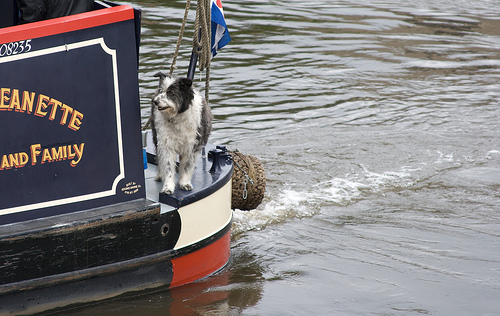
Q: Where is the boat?
A: Water.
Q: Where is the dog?
A: Boat.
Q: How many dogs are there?
A: One.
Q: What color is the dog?
A: White.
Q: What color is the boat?
A: Black.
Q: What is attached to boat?
A: Rope.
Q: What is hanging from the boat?
A: Flag.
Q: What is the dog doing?
A: Standing.